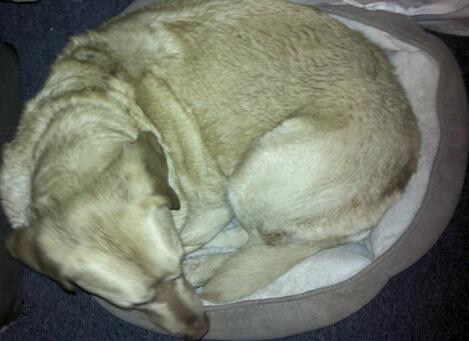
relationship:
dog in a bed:
[0, 1, 423, 340] [78, 0, 468, 340]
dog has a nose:
[0, 1, 423, 340] [175, 312, 216, 340]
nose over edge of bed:
[175, 312, 216, 340] [78, 0, 468, 340]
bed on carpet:
[78, 0, 468, 340] [1, 1, 131, 133]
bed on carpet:
[78, 0, 468, 340] [0, 254, 467, 337]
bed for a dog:
[78, 0, 468, 340] [0, 1, 423, 340]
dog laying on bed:
[0, 1, 423, 340] [78, 0, 468, 340]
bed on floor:
[78, 0, 468, 340] [2, 1, 469, 338]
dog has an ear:
[0, 1, 423, 340] [121, 129, 186, 218]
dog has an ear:
[0, 1, 423, 340] [5, 219, 82, 299]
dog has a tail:
[0, 1, 423, 340] [200, 227, 374, 306]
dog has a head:
[0, 1, 423, 340] [7, 129, 215, 340]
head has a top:
[7, 129, 215, 340] [31, 156, 125, 239]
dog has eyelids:
[0, 1, 423, 340] [119, 266, 186, 315]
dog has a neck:
[0, 1, 423, 340] [18, 110, 135, 201]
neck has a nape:
[18, 110, 135, 201] [24, 91, 119, 133]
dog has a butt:
[0, 1, 423, 340] [337, 100, 427, 254]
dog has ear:
[0, 1, 423, 340] [5, 226, 73, 298]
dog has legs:
[0, 1, 423, 340] [146, 107, 399, 309]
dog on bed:
[0, 1, 423, 340] [78, 0, 468, 340]